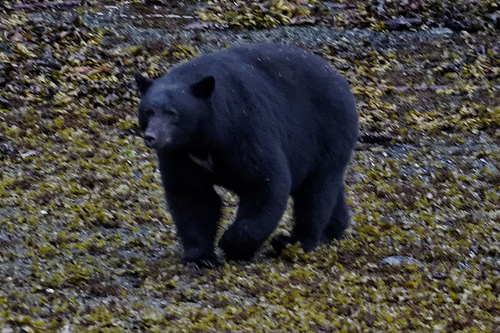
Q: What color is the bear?
A: Black.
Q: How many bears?
A: One.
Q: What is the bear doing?
A: Walking.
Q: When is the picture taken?
A: Daytime.